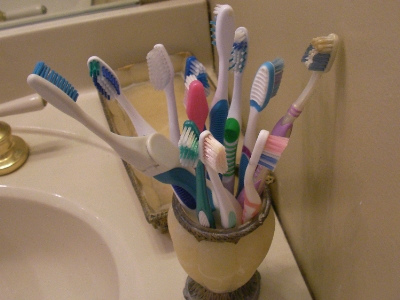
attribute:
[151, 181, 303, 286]
cup — gold, white, round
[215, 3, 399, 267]
wall — white, grey, tan, brown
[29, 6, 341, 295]
toothbrushes — white, blue, yellow, pink, purple, green, tall, plentyfull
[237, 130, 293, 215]
toothbrush — pink, white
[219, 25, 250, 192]
toothbrush — green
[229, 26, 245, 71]
bristles — blue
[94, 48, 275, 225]
dish — soap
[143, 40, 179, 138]
toothbrush — white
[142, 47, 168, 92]
bristles — white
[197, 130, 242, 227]
toothbrush — light, green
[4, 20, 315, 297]
sink — white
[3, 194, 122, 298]
indent — deep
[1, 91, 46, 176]
faucet — gold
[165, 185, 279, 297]
cup — round, brown